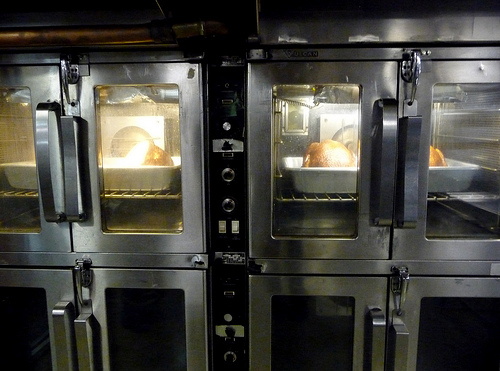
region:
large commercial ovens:
[25, 23, 496, 333]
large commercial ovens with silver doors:
[50, 28, 456, 369]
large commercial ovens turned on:
[17, 46, 492, 294]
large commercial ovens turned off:
[28, 247, 289, 364]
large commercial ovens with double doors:
[22, 7, 496, 262]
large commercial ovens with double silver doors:
[36, 19, 498, 310]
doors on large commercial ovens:
[24, 16, 482, 282]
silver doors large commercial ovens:
[32, 20, 482, 365]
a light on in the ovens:
[37, 20, 497, 272]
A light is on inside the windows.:
[264, 59, 496, 239]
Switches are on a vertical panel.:
[203, 57, 245, 366]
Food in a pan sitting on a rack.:
[277, 137, 357, 204]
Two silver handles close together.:
[49, 297, 97, 367]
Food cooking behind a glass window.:
[91, 82, 183, 232]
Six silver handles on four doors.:
[36, 57, 94, 369]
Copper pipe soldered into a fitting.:
[1, 10, 227, 49]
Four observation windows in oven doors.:
[0, 83, 498, 232]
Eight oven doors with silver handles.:
[0, 44, 497, 367]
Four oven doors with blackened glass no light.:
[0, 265, 498, 369]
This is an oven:
[77, 53, 182, 233]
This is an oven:
[261, 68, 375, 263]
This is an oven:
[426, 71, 498, 262]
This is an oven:
[277, 250, 375, 362]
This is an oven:
[420, 295, 492, 355]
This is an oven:
[104, 277, 200, 369]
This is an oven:
[9, 282, 69, 365]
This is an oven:
[13, 82, 84, 234]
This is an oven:
[405, 285, 470, 350]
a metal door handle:
[369, 92, 403, 232]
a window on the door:
[271, 79, 362, 240]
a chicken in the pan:
[298, 132, 361, 169]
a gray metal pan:
[280, 148, 360, 195]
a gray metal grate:
[272, 187, 359, 208]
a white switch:
[226, 217, 244, 237]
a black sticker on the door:
[278, 45, 323, 60]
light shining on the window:
[118, 133, 152, 171]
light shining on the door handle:
[378, 115, 397, 129]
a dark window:
[270, 290, 358, 369]